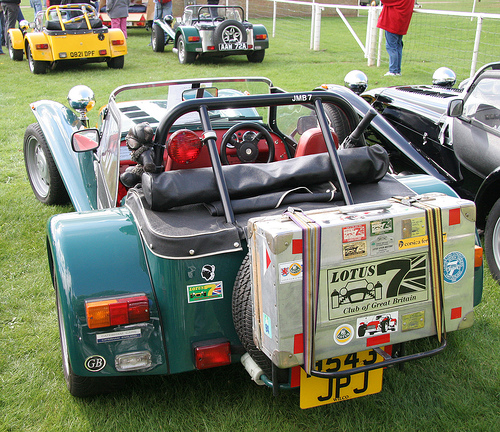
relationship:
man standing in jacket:
[376, 0, 409, 79] [375, 0, 411, 35]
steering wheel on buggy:
[219, 122, 274, 167] [20, 73, 485, 410]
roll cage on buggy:
[145, 81, 421, 202] [20, 73, 485, 410]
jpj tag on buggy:
[299, 348, 383, 409] [20, 73, 485, 410]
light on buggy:
[84, 295, 151, 328] [23, 75, 483, 409]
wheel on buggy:
[22, 121, 69, 209] [23, 75, 483, 409]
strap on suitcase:
[286, 195, 446, 374] [247, 192, 474, 369]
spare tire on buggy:
[228, 247, 285, 379] [23, 75, 483, 409]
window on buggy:
[91, 105, 123, 209] [23, 75, 483, 409]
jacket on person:
[377, 3, 414, 26] [373, 3, 419, 78]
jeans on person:
[377, 23, 416, 76] [373, 3, 419, 78]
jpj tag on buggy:
[289, 350, 396, 407] [23, 75, 483, 409]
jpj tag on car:
[299, 348, 383, 409] [87, 80, 413, 335]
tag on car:
[345, 53, 465, 92] [341, 46, 498, 208]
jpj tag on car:
[299, 348, 383, 409] [96, 58, 261, 158]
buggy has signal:
[23, 75, 483, 409] [180, 277, 237, 307]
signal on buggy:
[187, 281, 223, 304] [23, 75, 483, 409]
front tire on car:
[13, 118, 69, 206] [15, 58, 490, 410]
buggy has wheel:
[23, 75, 483, 409] [19, 127, 68, 208]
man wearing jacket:
[376, 0, 410, 79] [377, 0, 414, 34]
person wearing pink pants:
[112, 0, 136, 39] [107, 16, 134, 43]